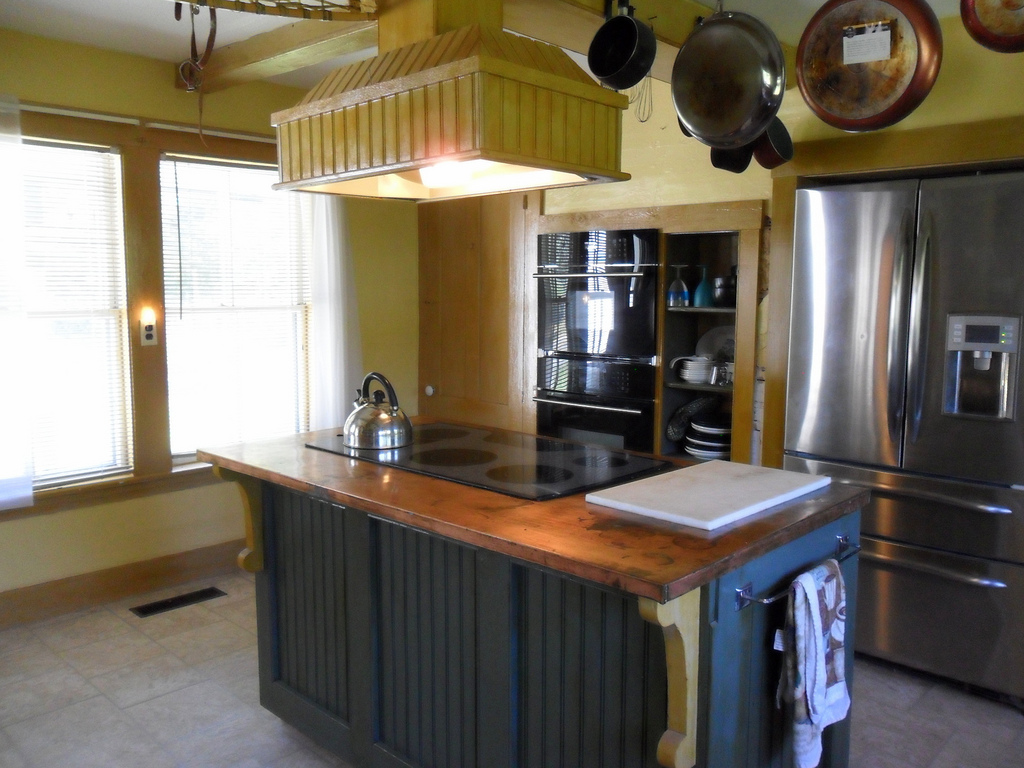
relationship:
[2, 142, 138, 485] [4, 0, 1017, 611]
window on wall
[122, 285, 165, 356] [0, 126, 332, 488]
outlet between scene